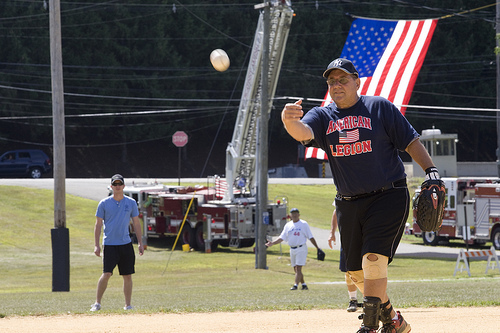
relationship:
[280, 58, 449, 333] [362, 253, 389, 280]
man wearing brace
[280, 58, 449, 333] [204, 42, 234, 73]
man throwing ball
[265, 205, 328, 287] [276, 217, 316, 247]
man wearing t-shirt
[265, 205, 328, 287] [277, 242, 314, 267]
man wearing pants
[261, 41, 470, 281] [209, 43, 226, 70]
man pitching ball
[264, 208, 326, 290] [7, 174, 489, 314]
man walking on grass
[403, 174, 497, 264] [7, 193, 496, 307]
truck parked near field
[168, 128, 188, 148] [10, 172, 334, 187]
sign on road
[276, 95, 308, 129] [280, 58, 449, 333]
hand on man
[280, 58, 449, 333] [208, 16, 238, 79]
man pitched ball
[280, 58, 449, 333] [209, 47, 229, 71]
man throwing ball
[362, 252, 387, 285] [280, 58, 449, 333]
brace on man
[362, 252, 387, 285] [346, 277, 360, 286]
brace on knee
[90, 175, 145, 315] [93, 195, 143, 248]
man with shirt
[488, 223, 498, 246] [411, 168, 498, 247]
wheel on vehicle